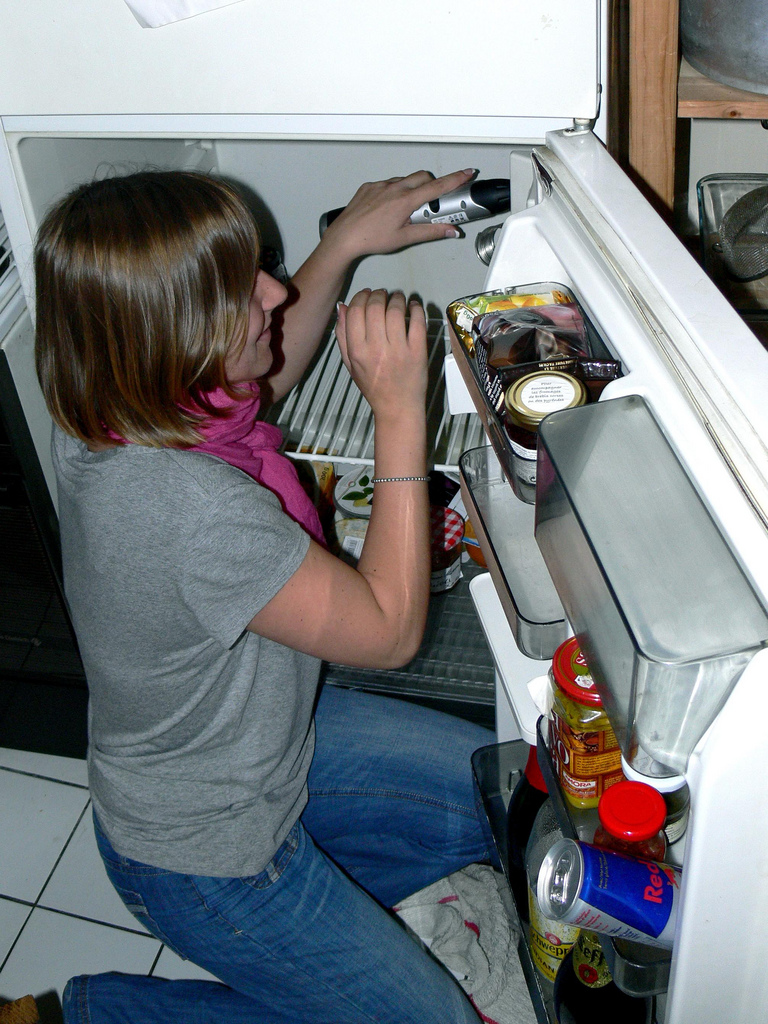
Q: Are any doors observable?
A: Yes, there is a door.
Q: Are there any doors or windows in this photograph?
A: Yes, there is a door.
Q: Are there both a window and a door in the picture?
A: No, there is a door but no windows.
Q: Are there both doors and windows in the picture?
A: No, there is a door but no windows.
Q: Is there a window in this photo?
A: No, there are no windows.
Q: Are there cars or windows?
A: No, there are no windows or cars.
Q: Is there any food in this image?
A: Yes, there is food.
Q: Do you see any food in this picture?
A: Yes, there is food.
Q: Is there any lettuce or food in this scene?
A: Yes, there is food.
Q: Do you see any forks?
A: No, there are no forks.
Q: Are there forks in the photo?
A: No, there are no forks.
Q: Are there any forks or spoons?
A: No, there are no forks or spoons.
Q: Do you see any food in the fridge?
A: Yes, there is food in the fridge.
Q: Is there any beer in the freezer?
A: No, there is food in the freezer.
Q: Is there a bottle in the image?
A: Yes, there is a bottle.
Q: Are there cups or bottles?
A: Yes, there is a bottle.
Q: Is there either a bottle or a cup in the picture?
A: Yes, there is a bottle.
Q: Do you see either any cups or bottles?
A: Yes, there is a bottle.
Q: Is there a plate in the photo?
A: No, there are no plates.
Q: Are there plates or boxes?
A: No, there are no plates or boxes.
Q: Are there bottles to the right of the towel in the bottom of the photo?
A: Yes, there is a bottle to the right of the towel.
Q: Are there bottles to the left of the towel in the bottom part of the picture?
A: No, the bottle is to the right of the towel.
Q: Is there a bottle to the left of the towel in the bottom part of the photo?
A: No, the bottle is to the right of the towel.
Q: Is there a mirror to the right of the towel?
A: No, there is a bottle to the right of the towel.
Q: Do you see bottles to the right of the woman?
A: Yes, there is a bottle to the right of the woman.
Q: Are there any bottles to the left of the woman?
A: No, the bottle is to the right of the woman.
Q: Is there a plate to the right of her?
A: No, there is a bottle to the right of the woman.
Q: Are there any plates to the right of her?
A: No, there is a bottle to the right of the woman.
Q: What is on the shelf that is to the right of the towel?
A: The bottle is on the shelf.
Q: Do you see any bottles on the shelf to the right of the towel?
A: Yes, there is a bottle on the shelf.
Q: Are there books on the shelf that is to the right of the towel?
A: No, there is a bottle on the shelf.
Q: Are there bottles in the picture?
A: Yes, there is a bottle.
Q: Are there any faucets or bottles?
A: Yes, there is a bottle.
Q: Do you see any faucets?
A: No, there are no faucets.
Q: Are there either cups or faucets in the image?
A: No, there are no faucets or cups.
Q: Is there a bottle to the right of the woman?
A: Yes, there is a bottle to the right of the woman.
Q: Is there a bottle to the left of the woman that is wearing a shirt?
A: No, the bottle is to the right of the woman.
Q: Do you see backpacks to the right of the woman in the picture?
A: No, there is a bottle to the right of the woman.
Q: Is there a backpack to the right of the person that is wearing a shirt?
A: No, there is a bottle to the right of the woman.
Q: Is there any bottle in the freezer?
A: Yes, there is a bottle in the freezer.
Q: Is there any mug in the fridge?
A: No, there is a bottle in the fridge.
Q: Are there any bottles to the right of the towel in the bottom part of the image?
A: Yes, there is a bottle to the right of the towel.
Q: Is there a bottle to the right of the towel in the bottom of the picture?
A: Yes, there is a bottle to the right of the towel.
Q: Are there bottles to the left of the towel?
A: No, the bottle is to the right of the towel.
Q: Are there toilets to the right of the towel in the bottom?
A: No, there is a bottle to the right of the towel.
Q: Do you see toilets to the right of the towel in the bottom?
A: No, there is a bottle to the right of the towel.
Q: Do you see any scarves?
A: Yes, there is a scarf.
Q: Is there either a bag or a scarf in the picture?
A: Yes, there is a scarf.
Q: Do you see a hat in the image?
A: No, there are no hats.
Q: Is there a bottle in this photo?
A: Yes, there is a bottle.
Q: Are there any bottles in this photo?
A: Yes, there is a bottle.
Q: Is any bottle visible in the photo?
A: Yes, there is a bottle.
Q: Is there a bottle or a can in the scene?
A: Yes, there is a bottle.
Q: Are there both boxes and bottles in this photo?
A: No, there is a bottle but no boxes.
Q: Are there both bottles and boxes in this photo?
A: No, there is a bottle but no boxes.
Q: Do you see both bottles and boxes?
A: No, there is a bottle but no boxes.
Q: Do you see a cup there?
A: No, there are no cups.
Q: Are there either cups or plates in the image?
A: No, there are no cups or plates.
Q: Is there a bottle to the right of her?
A: Yes, there is a bottle to the right of the woman.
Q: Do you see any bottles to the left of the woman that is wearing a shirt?
A: No, the bottle is to the right of the woman.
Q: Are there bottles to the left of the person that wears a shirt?
A: No, the bottle is to the right of the woman.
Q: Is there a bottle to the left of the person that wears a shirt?
A: No, the bottle is to the right of the woman.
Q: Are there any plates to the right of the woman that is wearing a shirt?
A: No, there is a bottle to the right of the woman.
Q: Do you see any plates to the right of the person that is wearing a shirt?
A: No, there is a bottle to the right of the woman.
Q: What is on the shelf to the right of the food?
A: The bottle is on the shelf.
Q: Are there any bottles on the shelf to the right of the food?
A: Yes, there is a bottle on the shelf.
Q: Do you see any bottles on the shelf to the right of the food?
A: Yes, there is a bottle on the shelf.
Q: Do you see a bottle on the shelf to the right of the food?
A: Yes, there is a bottle on the shelf.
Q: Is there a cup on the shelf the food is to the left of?
A: No, there is a bottle on the shelf.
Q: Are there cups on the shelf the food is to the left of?
A: No, there is a bottle on the shelf.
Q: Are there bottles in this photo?
A: Yes, there is a bottle.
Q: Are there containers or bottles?
A: Yes, there is a bottle.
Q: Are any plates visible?
A: No, there are no plates.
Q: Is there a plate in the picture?
A: No, there are no plates.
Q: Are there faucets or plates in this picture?
A: No, there are no plates or faucets.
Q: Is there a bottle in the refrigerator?
A: Yes, there is a bottle in the refrigerator.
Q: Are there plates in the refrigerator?
A: No, there is a bottle in the refrigerator.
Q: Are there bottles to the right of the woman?
A: Yes, there is a bottle to the right of the woman.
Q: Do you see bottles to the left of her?
A: No, the bottle is to the right of the woman.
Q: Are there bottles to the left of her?
A: No, the bottle is to the right of the woman.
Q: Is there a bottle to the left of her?
A: No, the bottle is to the right of the woman.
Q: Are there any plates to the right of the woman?
A: No, there is a bottle to the right of the woman.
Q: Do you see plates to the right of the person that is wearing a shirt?
A: No, there is a bottle to the right of the woman.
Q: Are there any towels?
A: Yes, there is a towel.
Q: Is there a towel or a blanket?
A: Yes, there is a towel.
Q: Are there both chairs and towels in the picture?
A: No, there is a towel but no chairs.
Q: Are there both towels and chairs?
A: No, there is a towel but no chairs.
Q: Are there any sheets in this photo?
A: No, there are no sheets.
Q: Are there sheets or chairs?
A: No, there are no sheets or chairs.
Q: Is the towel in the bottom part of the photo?
A: Yes, the towel is in the bottom of the image.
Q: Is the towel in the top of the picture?
A: No, the towel is in the bottom of the image.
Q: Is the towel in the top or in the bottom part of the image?
A: The towel is in the bottom of the image.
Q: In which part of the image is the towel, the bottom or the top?
A: The towel is in the bottom of the image.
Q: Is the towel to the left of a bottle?
A: Yes, the towel is to the left of a bottle.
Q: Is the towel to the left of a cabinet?
A: No, the towel is to the left of a bottle.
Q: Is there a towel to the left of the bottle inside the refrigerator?
A: Yes, there is a towel to the left of the bottle.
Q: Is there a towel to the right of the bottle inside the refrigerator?
A: No, the towel is to the left of the bottle.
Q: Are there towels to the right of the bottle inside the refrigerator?
A: No, the towel is to the left of the bottle.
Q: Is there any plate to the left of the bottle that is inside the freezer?
A: No, there is a towel to the left of the bottle.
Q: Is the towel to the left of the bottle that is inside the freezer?
A: Yes, the towel is to the left of the bottle.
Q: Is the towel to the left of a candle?
A: No, the towel is to the left of the bottle.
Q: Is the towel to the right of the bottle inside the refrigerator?
A: No, the towel is to the left of the bottle.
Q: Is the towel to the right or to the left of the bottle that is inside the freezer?
A: The towel is to the left of the bottle.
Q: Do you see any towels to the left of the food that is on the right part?
A: Yes, there is a towel to the left of the food.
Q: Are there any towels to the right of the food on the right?
A: No, the towel is to the left of the food.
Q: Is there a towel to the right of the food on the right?
A: No, the towel is to the left of the food.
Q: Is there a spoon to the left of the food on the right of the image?
A: No, there is a towel to the left of the food.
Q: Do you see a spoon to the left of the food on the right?
A: No, there is a towel to the left of the food.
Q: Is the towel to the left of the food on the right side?
A: Yes, the towel is to the left of the food.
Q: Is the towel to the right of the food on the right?
A: No, the towel is to the left of the food.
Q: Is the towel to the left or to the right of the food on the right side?
A: The towel is to the left of the food.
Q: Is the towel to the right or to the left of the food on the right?
A: The towel is to the left of the food.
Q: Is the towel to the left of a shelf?
A: Yes, the towel is to the left of a shelf.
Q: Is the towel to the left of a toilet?
A: No, the towel is to the left of a shelf.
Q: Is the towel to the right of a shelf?
A: No, the towel is to the left of a shelf.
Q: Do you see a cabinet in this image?
A: No, there are no cabinets.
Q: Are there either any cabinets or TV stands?
A: No, there are no cabinets or TV stands.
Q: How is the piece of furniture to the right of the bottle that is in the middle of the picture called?
A: The piece of furniture is a shelf.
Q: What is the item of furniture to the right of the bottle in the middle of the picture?
A: The piece of furniture is a shelf.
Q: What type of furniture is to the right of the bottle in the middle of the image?
A: The piece of furniture is a shelf.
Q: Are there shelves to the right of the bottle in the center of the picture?
A: Yes, there is a shelf to the right of the bottle.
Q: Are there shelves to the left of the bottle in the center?
A: No, the shelf is to the right of the bottle.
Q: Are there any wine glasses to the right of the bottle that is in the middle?
A: No, there is a shelf to the right of the bottle.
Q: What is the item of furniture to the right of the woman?
A: The piece of furniture is a shelf.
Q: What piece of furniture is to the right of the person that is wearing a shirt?
A: The piece of furniture is a shelf.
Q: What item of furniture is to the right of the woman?
A: The piece of furniture is a shelf.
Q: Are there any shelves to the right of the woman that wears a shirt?
A: Yes, there is a shelf to the right of the woman.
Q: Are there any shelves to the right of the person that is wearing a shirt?
A: Yes, there is a shelf to the right of the woman.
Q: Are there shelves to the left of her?
A: No, the shelf is to the right of the woman.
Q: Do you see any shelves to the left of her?
A: No, the shelf is to the right of the woman.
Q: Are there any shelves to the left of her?
A: No, the shelf is to the right of the woman.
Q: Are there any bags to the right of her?
A: No, there is a shelf to the right of the woman.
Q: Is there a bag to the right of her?
A: No, there is a shelf to the right of the woman.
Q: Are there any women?
A: Yes, there is a woman.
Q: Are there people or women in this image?
A: Yes, there is a woman.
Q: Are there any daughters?
A: No, there are no daughters.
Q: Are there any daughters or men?
A: No, there are no daughters or men.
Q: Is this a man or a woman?
A: This is a woman.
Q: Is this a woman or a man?
A: This is a woman.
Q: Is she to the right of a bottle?
A: No, the woman is to the left of a bottle.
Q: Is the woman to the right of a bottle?
A: No, the woman is to the left of a bottle.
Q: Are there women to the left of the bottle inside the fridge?
A: Yes, there is a woman to the left of the bottle.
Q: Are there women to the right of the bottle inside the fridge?
A: No, the woman is to the left of the bottle.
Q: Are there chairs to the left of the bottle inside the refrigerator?
A: No, there is a woman to the left of the bottle.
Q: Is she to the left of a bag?
A: No, the woman is to the left of a bottle.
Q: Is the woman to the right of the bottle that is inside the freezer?
A: No, the woman is to the left of the bottle.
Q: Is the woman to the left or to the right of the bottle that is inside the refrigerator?
A: The woman is to the left of the bottle.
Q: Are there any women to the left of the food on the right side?
A: Yes, there is a woman to the left of the food.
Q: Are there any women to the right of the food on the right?
A: No, the woman is to the left of the food.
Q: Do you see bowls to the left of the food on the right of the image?
A: No, there is a woman to the left of the food.